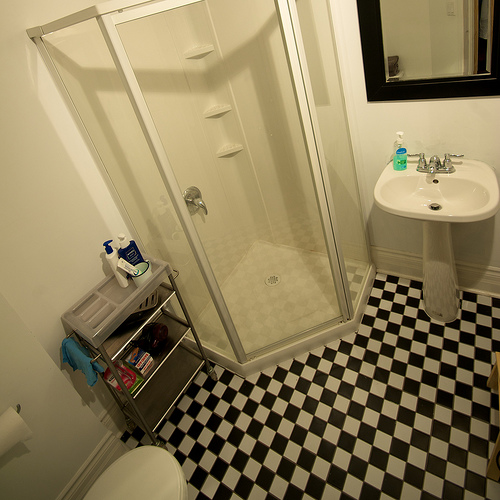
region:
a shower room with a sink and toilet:
[3, 26, 480, 498]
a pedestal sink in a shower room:
[371, 123, 495, 332]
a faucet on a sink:
[402, 145, 464, 182]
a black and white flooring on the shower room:
[263, 401, 460, 486]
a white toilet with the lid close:
[77, 440, 197, 496]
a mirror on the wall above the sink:
[345, 3, 498, 119]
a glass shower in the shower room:
[56, 70, 351, 165]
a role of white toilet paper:
[2, 400, 34, 455]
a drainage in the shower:
[259, 269, 284, 290]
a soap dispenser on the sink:
[391, 125, 410, 174]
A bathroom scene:
[4, 4, 494, 498]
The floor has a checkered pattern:
[120, 271, 497, 498]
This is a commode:
[76, 445, 193, 499]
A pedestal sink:
[373, 125, 498, 324]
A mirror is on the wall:
[354, 0, 498, 103]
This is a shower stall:
[26, 1, 377, 377]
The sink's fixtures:
[406, 148, 466, 175]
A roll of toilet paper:
[0, 401, 36, 455]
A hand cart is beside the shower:
[61, 233, 218, 448]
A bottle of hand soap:
[389, 128, 410, 170]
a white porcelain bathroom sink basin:
[374, 155, 499, 227]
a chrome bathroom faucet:
[404, 147, 461, 176]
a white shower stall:
[32, 2, 375, 380]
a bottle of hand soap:
[391, 130, 408, 172]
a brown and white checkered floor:
[158, 270, 497, 497]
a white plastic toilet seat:
[83, 439, 186, 498]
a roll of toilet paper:
[0, 403, 36, 455]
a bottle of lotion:
[101, 237, 128, 287]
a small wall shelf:
[202, 98, 230, 119]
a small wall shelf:
[217, 135, 242, 159]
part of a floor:
[423, 416, 440, 438]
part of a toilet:
[157, 460, 185, 476]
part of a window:
[227, 249, 230, 294]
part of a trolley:
[166, 355, 185, 368]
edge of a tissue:
[20, 411, 32, 428]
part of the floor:
[353, 415, 402, 473]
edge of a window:
[326, 284, 341, 305]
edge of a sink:
[433, 218, 469, 320]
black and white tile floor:
[120, 271, 498, 497]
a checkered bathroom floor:
[120, 268, 497, 495]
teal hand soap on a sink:
[386, 127, 407, 169]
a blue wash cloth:
[55, 333, 105, 384]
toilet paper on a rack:
[0, 401, 33, 456]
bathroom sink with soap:
[370, 125, 498, 325]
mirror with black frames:
[355, 0, 495, 100]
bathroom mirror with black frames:
[352, 0, 492, 100]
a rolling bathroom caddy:
[51, 226, 218, 449]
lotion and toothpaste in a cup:
[93, 228, 161, 293]